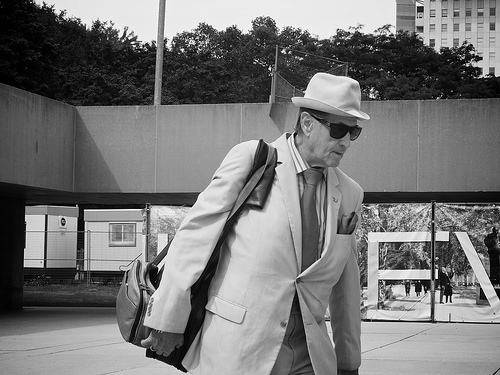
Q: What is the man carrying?
A: A bag.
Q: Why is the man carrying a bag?
A: He needs to hold something.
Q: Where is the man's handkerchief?
A: In the suit pocket.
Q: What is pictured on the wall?
A: Giant letters.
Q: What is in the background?
A: A tall building.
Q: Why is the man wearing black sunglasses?
A: It is sunny.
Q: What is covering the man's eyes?
A: Black sunglasses.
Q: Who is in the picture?
A: An old man.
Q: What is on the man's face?
A: Glasses.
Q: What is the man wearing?
A: Suit and tie.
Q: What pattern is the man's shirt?
A: Striped.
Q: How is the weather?
A: Clear.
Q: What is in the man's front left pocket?
A: A hankerchief.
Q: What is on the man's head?
A: A hat.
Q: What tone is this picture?
A: Black and white.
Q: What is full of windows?
A: Building.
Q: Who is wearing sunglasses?
A: The man.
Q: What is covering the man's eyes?
A: Sunglasses.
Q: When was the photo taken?
A: Daytime.